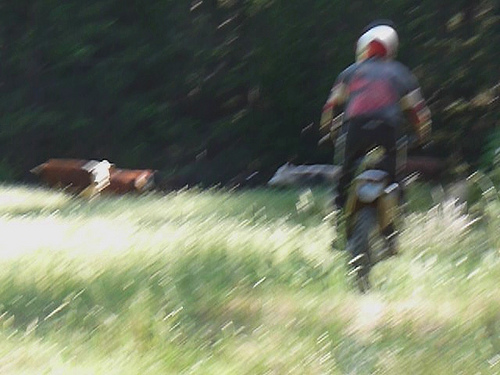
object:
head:
[81, 158, 112, 189]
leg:
[332, 123, 374, 235]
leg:
[379, 126, 408, 221]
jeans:
[333, 112, 412, 214]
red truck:
[63, 175, 158, 201]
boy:
[321, 22, 431, 255]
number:
[344, 69, 390, 116]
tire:
[347, 205, 375, 292]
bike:
[348, 171, 396, 291]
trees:
[0, 2, 496, 184]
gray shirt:
[337, 62, 414, 121]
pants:
[335, 120, 405, 207]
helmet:
[352, 24, 399, 58]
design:
[335, 66, 399, 118]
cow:
[103, 166, 155, 194]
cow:
[30, 157, 153, 195]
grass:
[1, 182, 500, 375]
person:
[319, 25, 434, 293]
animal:
[264, 162, 335, 187]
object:
[32, 159, 156, 200]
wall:
[30, 46, 264, 141]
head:
[268, 160, 306, 187]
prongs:
[363, 231, 399, 285]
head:
[354, 23, 399, 61]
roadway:
[413, 162, 468, 187]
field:
[0, 170, 500, 348]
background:
[0, 0, 500, 185]